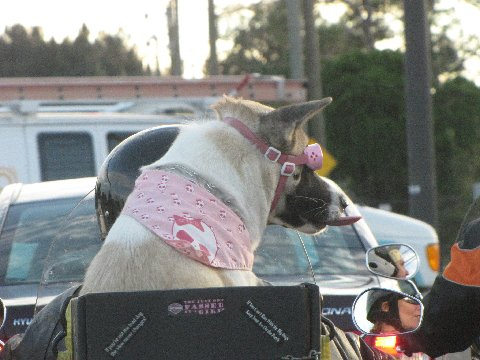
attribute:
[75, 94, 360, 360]
dog — white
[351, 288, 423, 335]
mirror — side view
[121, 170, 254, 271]
scarf — pink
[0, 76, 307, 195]
van — white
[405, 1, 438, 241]
pole — tall, brown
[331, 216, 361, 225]
tongue — out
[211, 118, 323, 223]
goggles — pink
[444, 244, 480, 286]
stripe — orange